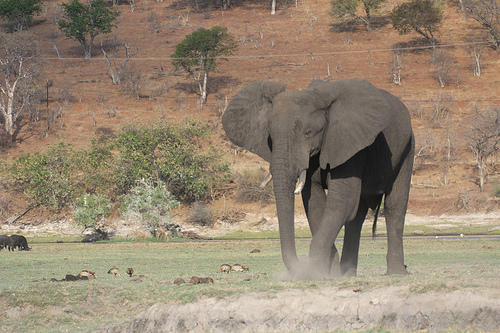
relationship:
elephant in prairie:
[172, 69, 423, 286] [70, 213, 434, 329]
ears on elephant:
[227, 81, 417, 174] [232, 63, 467, 304]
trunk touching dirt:
[259, 164, 308, 276] [1, 231, 500, 331]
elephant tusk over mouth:
[288, 160, 317, 205] [272, 150, 341, 210]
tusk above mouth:
[258, 166, 279, 195] [258, 153, 334, 231]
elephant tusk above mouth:
[293, 168, 307, 194] [258, 153, 334, 231]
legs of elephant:
[296, 151, 356, 276] [216, 75, 428, 307]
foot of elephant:
[299, 173, 344, 276] [212, 68, 417, 309]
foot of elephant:
[307, 262, 334, 280] [212, 68, 417, 309]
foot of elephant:
[343, 208, 368, 273] [212, 68, 417, 309]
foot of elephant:
[376, 177, 421, 273] [212, 68, 417, 309]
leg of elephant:
[339, 202, 371, 276] [205, 64, 443, 304]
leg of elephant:
[372, 177, 421, 278] [205, 64, 443, 304]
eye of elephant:
[294, 120, 321, 149] [205, 64, 443, 304]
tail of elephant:
[361, 195, 386, 245] [205, 64, 443, 304]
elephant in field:
[220, 77, 417, 278] [1, 0, 497, 330]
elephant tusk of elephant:
[293, 168, 307, 194] [220, 77, 417, 278]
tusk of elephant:
[259, 174, 274, 187] [220, 77, 417, 278]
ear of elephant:
[224, 80, 284, 158] [220, 77, 417, 278]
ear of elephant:
[315, 82, 385, 176] [220, 77, 417, 278]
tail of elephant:
[371, 195, 383, 241] [220, 77, 417, 278]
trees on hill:
[53, 2, 243, 103] [2, 4, 496, 225]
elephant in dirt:
[220, 77, 417, 278] [1, 231, 497, 331]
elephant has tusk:
[220, 77, 417, 278] [259, 173, 309, 196]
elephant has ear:
[220, 77, 417, 278] [224, 84, 278, 160]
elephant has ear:
[220, 77, 417, 278] [313, 93, 385, 173]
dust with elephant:
[188, 249, 430, 321] [205, 64, 443, 304]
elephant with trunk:
[220, 77, 417, 278] [268, 152, 330, 294]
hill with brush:
[50, 13, 223, 233] [54, 140, 248, 234]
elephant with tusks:
[220, 77, 417, 278] [259, 159, 355, 216]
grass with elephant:
[210, 221, 496, 280] [235, 73, 447, 283]